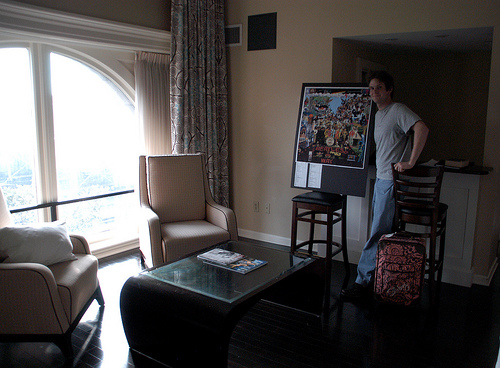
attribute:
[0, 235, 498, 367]
floor — present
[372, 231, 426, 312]
luggage — pink, present, floral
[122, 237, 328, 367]
table — present, black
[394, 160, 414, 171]
hand — present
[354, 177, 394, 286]
trouser — present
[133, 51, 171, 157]
curtain — back, present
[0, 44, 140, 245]
window — displayed, present, arched, large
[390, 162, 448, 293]
stool — tall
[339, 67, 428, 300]
man — present, smiling, standing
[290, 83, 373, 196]
photograph — black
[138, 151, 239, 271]
chair — beige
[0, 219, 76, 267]
pillow — wrinkled, white, square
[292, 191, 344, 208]
seat — black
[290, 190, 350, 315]
stool — present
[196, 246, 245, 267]
magazine — stacked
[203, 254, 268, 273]
magazine — stacked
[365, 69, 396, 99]
hair — dark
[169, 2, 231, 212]
drapes — long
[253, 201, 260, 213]
socket — unused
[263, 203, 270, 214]
socket — unused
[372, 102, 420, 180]
shirt — present, grey, gray, glass